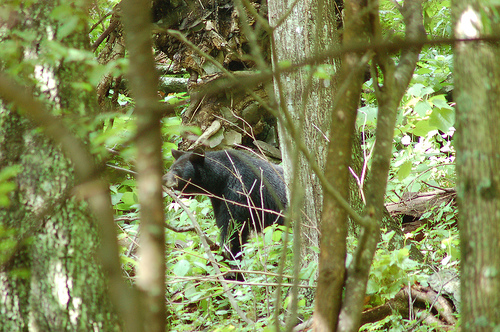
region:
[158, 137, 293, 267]
black bear looking to the left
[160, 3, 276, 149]
large tree in front of the bear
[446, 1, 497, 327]
tree with moss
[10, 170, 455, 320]
leaves and shrubs on the ground of the forest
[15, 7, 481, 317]
a dense forest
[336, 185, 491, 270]
piece of a log on the ground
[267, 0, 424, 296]
large tree in the forest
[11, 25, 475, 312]
forest during the daytime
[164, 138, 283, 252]
a black bear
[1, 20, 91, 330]
a tree bark on left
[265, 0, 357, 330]
a thick tree on right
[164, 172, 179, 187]
nose of bear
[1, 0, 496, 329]
a green forest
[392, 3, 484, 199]
sun shining bright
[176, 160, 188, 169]
the eyes are open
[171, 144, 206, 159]
two ears standing up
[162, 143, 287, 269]
bear looking to left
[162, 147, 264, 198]
A bear in the woods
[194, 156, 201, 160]
Shadow from the ear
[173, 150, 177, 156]
Ear facing forward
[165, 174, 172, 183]
The snout of the bear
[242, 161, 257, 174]
Black fur on the back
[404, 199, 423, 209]
A dry log on the ground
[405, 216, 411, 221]
A hole in the log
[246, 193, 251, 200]
Dry twigs next to the bear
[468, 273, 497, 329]
The bark of a tree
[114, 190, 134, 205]
Green leaves in the brushes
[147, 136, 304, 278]
This is a bear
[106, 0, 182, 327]
Trunk of a tree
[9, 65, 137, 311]
Trunk of a tree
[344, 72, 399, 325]
Trunk of a tree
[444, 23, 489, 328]
Trunk of a tree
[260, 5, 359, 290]
Trunk of a tree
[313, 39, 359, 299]
Trunk of a tree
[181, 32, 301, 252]
Trunk of a tree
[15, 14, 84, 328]
Trunk of a tree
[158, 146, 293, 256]
Black bear in a forest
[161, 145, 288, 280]
Alert bear standing among trees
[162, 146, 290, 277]
Ursine predator in natural habitat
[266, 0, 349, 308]
Smooth barked tree trunk with green lichen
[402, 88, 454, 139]
Frond of large green leaves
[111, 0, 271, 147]
Hillside above and behind bear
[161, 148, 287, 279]
Omnivorous mammal in wooded area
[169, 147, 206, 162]
Alert ears of large black bear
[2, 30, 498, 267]
Blurred twig reaching across frame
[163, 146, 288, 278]
Hungry bear on the prowl for food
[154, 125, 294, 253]
black bear in woods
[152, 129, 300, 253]
black bear in woods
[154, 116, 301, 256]
black bear in woods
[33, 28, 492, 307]
a scene during the day time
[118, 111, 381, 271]
a black bear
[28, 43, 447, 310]
a scene in the forest